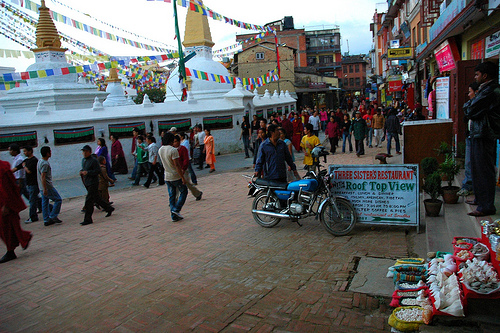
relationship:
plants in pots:
[419, 158, 446, 182] [414, 176, 442, 227]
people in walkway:
[112, 132, 180, 190] [269, 253, 331, 329]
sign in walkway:
[322, 166, 465, 280] [269, 253, 331, 329]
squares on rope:
[16, 53, 86, 96] [64, 45, 132, 67]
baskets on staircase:
[389, 245, 482, 330] [422, 210, 483, 244]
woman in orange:
[205, 112, 218, 167] [206, 130, 227, 147]